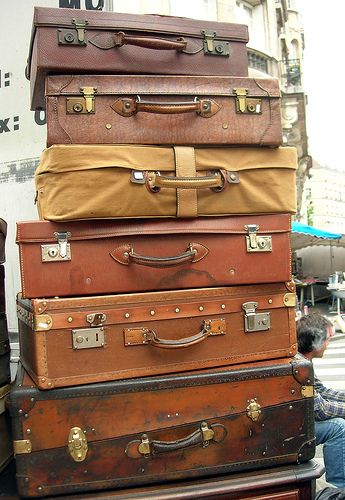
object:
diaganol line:
[16, 396, 311, 452]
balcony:
[280, 57, 305, 97]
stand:
[48, 456, 324, 498]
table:
[0, 216, 15, 374]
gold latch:
[67, 423, 89, 459]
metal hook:
[67, 327, 108, 353]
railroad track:
[315, 333, 345, 481]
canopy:
[287, 209, 341, 252]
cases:
[46, 74, 285, 146]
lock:
[70, 313, 108, 350]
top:
[25, 5, 247, 81]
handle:
[114, 29, 189, 55]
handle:
[112, 99, 218, 121]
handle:
[148, 170, 227, 188]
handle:
[135, 324, 233, 350]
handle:
[130, 427, 210, 456]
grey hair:
[310, 326, 322, 350]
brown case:
[5, 357, 316, 475]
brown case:
[17, 218, 293, 292]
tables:
[296, 276, 319, 308]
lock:
[246, 398, 261, 421]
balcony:
[241, 46, 278, 84]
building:
[0, 1, 311, 201]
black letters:
[60, 0, 110, 13]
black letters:
[0, 114, 13, 135]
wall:
[0, 0, 113, 303]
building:
[310, 167, 344, 234]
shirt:
[295, 349, 344, 419]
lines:
[316, 352, 343, 391]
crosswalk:
[309, 328, 343, 445]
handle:
[128, 92, 207, 124]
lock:
[56, 24, 86, 44]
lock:
[201, 37, 229, 56]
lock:
[234, 95, 263, 114]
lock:
[63, 97, 95, 113]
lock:
[245, 235, 273, 254]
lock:
[38, 243, 72, 264]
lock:
[243, 312, 271, 332]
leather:
[16, 278, 295, 377]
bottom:
[2, 458, 344, 498]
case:
[16, 278, 295, 386]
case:
[34, 144, 298, 219]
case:
[14, 4, 248, 75]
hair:
[295, 314, 328, 349]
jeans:
[307, 415, 343, 489]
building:
[1, 0, 340, 341]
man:
[299, 313, 344, 489]